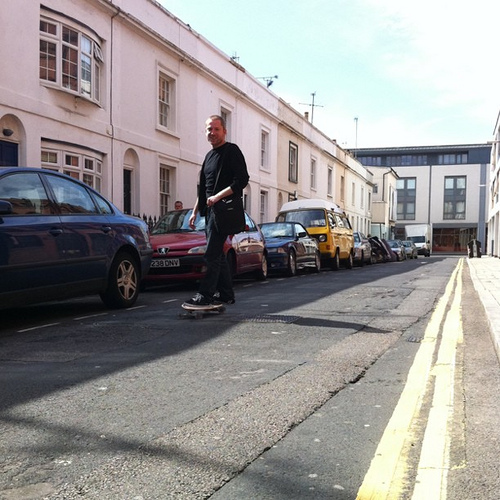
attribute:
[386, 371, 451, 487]
line — yellow, white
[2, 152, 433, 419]
road — parked, cracked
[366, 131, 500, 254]
building — white, long, townhouse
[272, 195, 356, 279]
bus — yellow, whitish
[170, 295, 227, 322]
stakeboard — white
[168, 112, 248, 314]
man — bald, dressed, walking, skateboarding, smiling, wearing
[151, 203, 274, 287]
car — red, parked, parked\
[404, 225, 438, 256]
truck — white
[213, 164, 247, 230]
bag — messanger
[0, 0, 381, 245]
building — pink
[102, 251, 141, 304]
tire — black